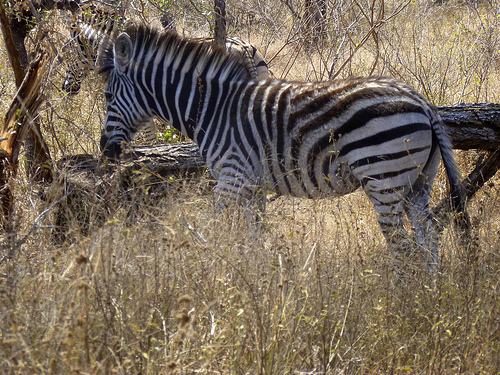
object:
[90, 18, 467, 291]
zebra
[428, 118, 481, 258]
tail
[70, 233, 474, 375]
grass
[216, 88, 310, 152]
stripes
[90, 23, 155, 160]
head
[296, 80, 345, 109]
hair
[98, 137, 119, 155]
nose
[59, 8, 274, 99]
zebra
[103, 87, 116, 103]
eye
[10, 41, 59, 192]
branch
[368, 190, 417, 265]
leg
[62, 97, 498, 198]
log